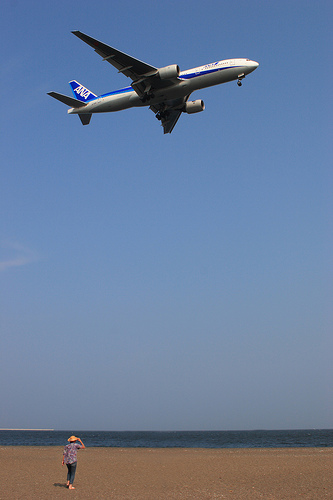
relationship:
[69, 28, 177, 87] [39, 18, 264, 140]
wing of plane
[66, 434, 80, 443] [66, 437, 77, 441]
hat with brim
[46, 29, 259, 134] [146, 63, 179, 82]
aircraft has engine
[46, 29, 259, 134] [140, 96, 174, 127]
aircraft has gear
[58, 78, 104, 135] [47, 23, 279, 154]
tail wing on plane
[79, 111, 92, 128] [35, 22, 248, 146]
tail wing on plane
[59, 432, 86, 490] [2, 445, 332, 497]
person on beach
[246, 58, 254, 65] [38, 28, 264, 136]
cockpit in airplane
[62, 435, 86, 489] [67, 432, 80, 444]
person wearing hat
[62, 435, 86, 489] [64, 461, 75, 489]
person wearing jeans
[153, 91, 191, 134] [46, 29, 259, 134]
wing of aircraft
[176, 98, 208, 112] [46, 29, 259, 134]
engine of a aircraft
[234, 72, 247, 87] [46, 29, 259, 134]
landing gear of a aircraft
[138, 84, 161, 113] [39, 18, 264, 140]
gear of a plane